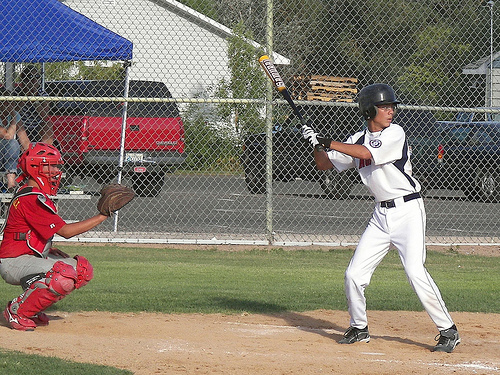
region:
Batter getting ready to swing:
[260, 55, 462, 350]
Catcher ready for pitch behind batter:
[2, 142, 136, 328]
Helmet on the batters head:
[354, 83, 399, 123]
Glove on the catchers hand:
[97, 186, 137, 213]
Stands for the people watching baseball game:
[4, 97, 89, 211]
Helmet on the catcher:
[19, 142, 64, 194]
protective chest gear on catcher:
[4, 187, 56, 257]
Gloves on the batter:
[299, 123, 330, 148]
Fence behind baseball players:
[1, 2, 497, 247]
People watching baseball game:
[1, 69, 56, 190]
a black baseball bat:
[256, 49, 318, 141]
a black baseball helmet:
[350, 80, 398, 123]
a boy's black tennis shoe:
[338, 327, 373, 345]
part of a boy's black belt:
[377, 190, 422, 210]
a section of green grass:
[93, 237, 498, 311]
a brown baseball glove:
[91, 180, 138, 215]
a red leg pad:
[20, 262, 79, 317]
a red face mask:
[32, 151, 64, 190]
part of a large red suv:
[46, 78, 189, 187]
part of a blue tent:
[0, 3, 135, 71]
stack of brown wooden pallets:
[292, 62, 357, 102]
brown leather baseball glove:
[91, 176, 142, 216]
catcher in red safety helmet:
[20, 135, 70, 192]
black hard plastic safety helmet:
[340, 75, 411, 120]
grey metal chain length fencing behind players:
[182, 101, 267, 236]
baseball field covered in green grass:
[120, 246, 285, 286]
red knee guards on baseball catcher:
[7, 251, 107, 327]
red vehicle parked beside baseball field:
[56, 71, 196, 161]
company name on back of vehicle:
[145, 135, 185, 149]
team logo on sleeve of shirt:
[366, 134, 387, 156]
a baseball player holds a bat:
[254, 33, 469, 358]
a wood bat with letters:
[247, 43, 332, 163]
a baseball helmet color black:
[348, 77, 411, 139]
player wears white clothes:
[290, 70, 473, 356]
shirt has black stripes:
[317, 125, 424, 207]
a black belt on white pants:
[371, 188, 428, 213]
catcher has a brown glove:
[3, 135, 143, 335]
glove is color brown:
[91, 178, 136, 220]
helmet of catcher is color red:
[10, 135, 77, 215]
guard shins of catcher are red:
[8, 255, 102, 329]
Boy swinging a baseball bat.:
[250, 45, 465, 357]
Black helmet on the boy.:
[351, 80, 401, 130]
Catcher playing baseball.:
[1, 135, 138, 335]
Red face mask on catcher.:
[20, 132, 70, 202]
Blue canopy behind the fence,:
[0, 0, 140, 73]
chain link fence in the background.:
[0, 0, 496, 248]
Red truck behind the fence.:
[35, 71, 187, 195]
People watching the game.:
[1, 64, 58, 188]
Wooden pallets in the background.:
[287, 72, 357, 104]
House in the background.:
[5, 0, 290, 161]